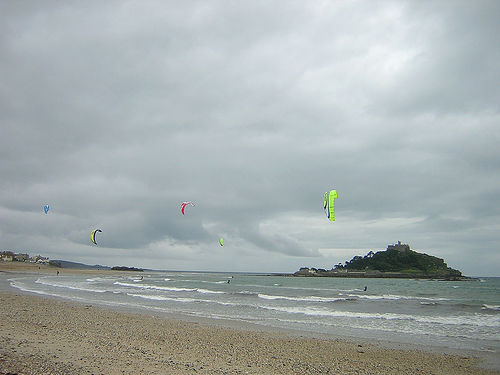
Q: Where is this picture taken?
A: The beach.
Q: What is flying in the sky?
A: Kites.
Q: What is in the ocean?
A: An Island.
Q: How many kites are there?
A: Five.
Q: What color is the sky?
A: Gray.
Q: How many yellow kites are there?
A: 3.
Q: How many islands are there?
A: One.